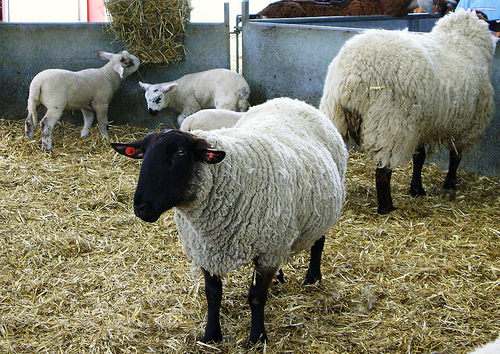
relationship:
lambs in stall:
[26, 59, 204, 135] [44, 18, 366, 228]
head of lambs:
[128, 110, 229, 233] [26, 59, 204, 135]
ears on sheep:
[101, 146, 134, 152] [51, 62, 394, 255]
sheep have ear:
[51, 62, 394, 255] [88, 122, 163, 179]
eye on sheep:
[163, 131, 205, 179] [51, 62, 394, 255]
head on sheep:
[128, 110, 229, 233] [51, 62, 394, 255]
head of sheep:
[128, 110, 229, 233] [51, 62, 394, 255]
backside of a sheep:
[316, 30, 400, 215] [320, 5, 485, 217]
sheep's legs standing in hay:
[198, 237, 324, 340] [334, 226, 484, 351]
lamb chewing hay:
[25, 50, 143, 151] [109, 0, 194, 49]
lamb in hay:
[107, 92, 353, 343] [0, 229, 170, 351]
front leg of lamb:
[195, 270, 225, 346] [107, 92, 353, 343]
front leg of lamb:
[243, 274, 275, 344] [107, 92, 353, 343]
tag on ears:
[122, 143, 139, 159] [110, 143, 144, 159]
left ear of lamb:
[198, 149, 228, 164] [107, 92, 353, 343]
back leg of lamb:
[297, 241, 327, 289] [107, 92, 353, 343]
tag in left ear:
[203, 142, 217, 166] [202, 148, 229, 161]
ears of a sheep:
[110, 143, 144, 159] [111, 87, 349, 338]